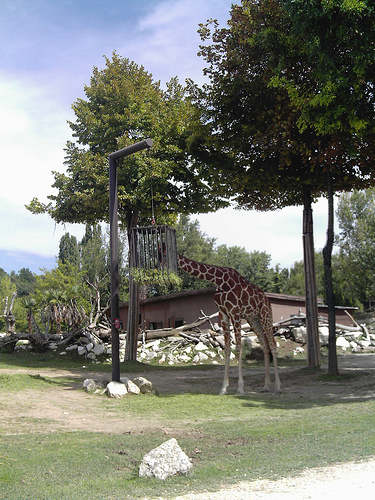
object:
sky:
[0, 0, 375, 278]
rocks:
[106, 380, 128, 398]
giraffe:
[157, 241, 283, 396]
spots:
[241, 289, 250, 305]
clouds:
[0, 87, 48, 141]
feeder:
[131, 225, 178, 287]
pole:
[109, 155, 120, 382]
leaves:
[297, 40, 308, 49]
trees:
[185, 16, 375, 376]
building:
[106, 292, 360, 332]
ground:
[0, 354, 375, 500]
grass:
[98, 451, 104, 458]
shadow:
[0, 348, 375, 411]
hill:
[0, 249, 67, 278]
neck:
[176, 253, 223, 290]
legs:
[231, 318, 242, 351]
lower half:
[237, 353, 244, 385]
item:
[111, 318, 122, 331]